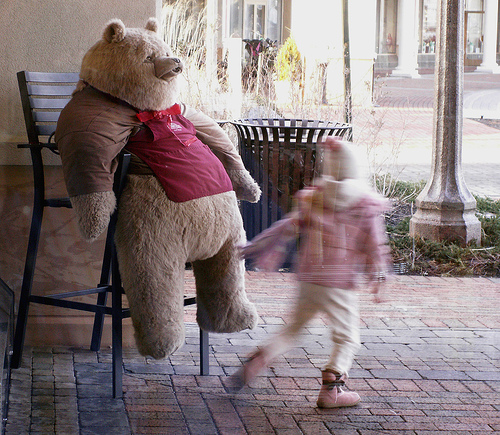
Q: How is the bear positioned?
A: Sitting.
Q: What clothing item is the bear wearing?
A: A apron.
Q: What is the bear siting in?
A: A chair.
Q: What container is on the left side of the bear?
A: Garbage can.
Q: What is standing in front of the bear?
A: A little girl.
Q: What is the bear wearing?
A: A brown t-shirt.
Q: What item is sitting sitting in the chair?
A: A teddy bear.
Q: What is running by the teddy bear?
A: A little girl.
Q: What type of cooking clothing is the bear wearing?
A: An apron.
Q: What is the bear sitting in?
A: A black chair.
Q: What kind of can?
A: Trash.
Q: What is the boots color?
A: Pink.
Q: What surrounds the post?
A: Grass.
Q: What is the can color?
A: Black.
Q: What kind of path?
A: Brick.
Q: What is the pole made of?
A: Concrete.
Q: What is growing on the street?
A: Weeds.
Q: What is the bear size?
A: Large.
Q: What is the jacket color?
A: Pink.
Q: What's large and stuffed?
A: Bear.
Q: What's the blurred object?
A: Small child.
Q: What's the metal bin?
A: Trash can.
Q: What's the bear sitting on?
A: Tall chair.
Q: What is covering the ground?
A: Bricks.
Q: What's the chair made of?
A: Metal.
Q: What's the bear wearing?
A: Apron.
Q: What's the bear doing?
A: Sitting.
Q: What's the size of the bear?
A: Large.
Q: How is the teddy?
A: Sitting.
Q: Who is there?
A: A little girl.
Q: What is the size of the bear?
A: Huge.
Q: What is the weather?
A: Cool.